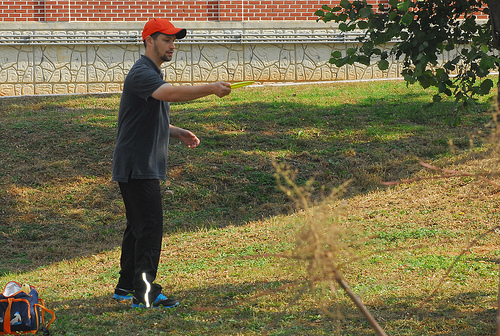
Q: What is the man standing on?
A: Grass.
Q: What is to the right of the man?
A: Tree.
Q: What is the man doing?
A: Throwing a frisbee.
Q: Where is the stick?
A: In front.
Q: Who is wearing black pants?
A: The man.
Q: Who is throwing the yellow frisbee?
A: The man.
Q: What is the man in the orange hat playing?
A: Frisbee.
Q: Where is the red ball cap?
A: On the man's head.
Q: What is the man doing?
A: Playing frisbee.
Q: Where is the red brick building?
A: At the top of the photo in the background.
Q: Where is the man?
A: In a grassy field.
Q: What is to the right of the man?
A: A tree with just the leaves showing.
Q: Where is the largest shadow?
A: Behind the man.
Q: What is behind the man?
A: A blue and orange bag.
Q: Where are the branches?
A: At the front of the photo.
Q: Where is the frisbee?
A: In the man's hand.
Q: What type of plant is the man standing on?
A: Grass.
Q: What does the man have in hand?
A: Frisbee.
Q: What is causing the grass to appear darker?
A: Shade.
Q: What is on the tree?
A: Leaves.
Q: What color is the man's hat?
A: Orange.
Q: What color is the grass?
A: Green.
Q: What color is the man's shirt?
A: Gray.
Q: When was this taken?
A: Daytime.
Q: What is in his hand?
A: Frisbee.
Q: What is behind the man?
A: A building.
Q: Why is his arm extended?
A: Throwing a frisbee.